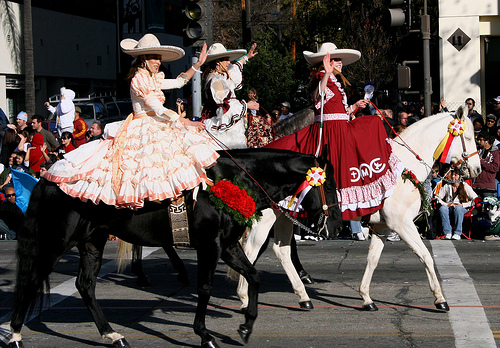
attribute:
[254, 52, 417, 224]
dress — red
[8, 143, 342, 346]
horse — black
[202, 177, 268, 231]
decoration — red, green, floral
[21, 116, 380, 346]
horse — white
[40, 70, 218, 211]
dress — peach, white, traditional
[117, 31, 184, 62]
sombrero — tan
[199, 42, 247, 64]
sombrero — tan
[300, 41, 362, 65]
sombrero — tan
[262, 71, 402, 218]
mexican dress. — traditional, red, white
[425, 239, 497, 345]
line — white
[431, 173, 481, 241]
chair — red